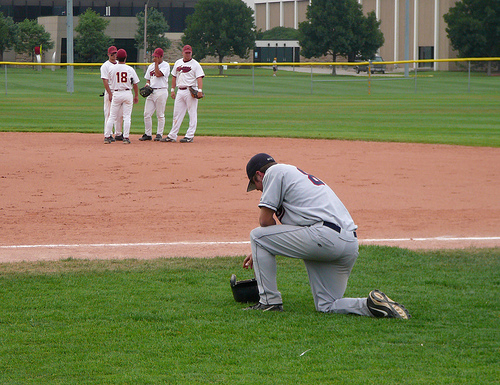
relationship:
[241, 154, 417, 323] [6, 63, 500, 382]
baseball player kneeling on ground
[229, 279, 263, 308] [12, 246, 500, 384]
baseball glove on grass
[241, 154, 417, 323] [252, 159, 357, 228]
baseball player wearing uniform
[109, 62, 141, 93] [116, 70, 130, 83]
uniform has number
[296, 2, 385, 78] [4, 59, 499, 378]
tree in baseball field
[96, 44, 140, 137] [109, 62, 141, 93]
baseball player wearing uniform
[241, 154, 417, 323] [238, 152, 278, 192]
baseball player wearing hat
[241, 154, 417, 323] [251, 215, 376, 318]
baseball player wearing pants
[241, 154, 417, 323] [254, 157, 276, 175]
baseball player has hair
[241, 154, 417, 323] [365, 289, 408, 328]
baseball player wearing shoe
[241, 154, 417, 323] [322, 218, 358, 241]
baseball player wearing belt